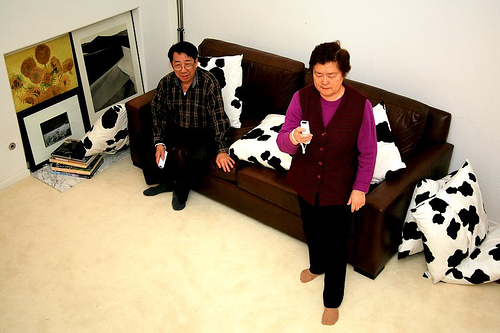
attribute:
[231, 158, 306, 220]
cushion — white , black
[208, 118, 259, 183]
cushion — black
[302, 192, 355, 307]
pants — dark  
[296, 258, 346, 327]
feet — bare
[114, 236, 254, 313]
floor — beige 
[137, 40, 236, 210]
man — seated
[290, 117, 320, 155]
phone — white 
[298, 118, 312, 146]
game control — white 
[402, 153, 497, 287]
pillow — white pattern, black pattern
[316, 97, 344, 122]
top — purple 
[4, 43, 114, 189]
black frame — Black 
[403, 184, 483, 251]
pillow — black pattern, white pattern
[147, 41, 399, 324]
two people — playing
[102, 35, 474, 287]
couch — brown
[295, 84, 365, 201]
vest — dark  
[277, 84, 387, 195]
shirt — purple 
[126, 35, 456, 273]
sofa — brown 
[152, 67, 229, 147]
shirt — black , striped 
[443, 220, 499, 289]
cow pillows — cow patterned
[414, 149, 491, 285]
cow pillows — cow patterned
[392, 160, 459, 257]
cow pillows — cow patterned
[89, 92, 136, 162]
cow pillows — cow patterned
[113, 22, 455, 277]
sofa — brown 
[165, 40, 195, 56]
hair — black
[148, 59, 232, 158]
shirt — flannel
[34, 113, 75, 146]
photo — Black , white 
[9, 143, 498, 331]
carpet — cream 